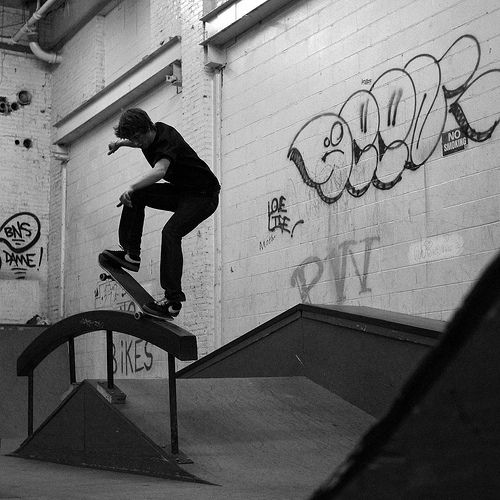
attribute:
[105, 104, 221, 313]
man — skating, close, looking, white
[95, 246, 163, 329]
board — black, small, long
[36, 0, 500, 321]
wall — white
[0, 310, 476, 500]
ramp — brown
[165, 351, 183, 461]
bar — metal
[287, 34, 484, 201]
graffiti — black, white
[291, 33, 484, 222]
graffiti — black, white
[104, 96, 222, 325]
man — skateboarding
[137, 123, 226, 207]
shirt — black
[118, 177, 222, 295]
pants — black